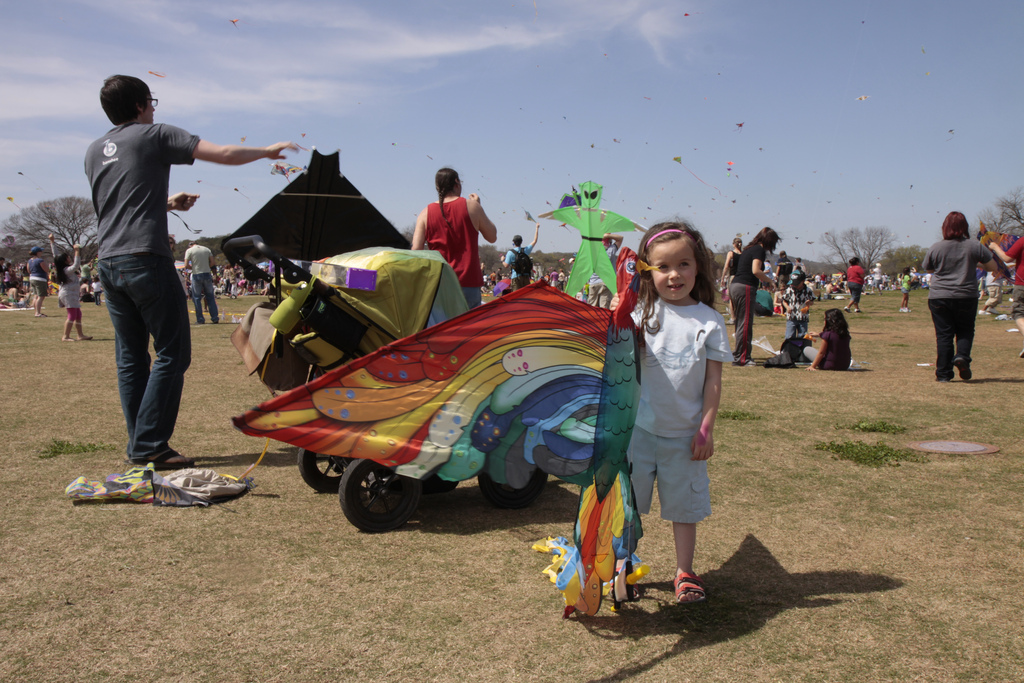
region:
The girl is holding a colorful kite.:
[220, 220, 759, 623]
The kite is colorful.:
[212, 253, 669, 607]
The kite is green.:
[528, 177, 640, 299]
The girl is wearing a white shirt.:
[612, 211, 731, 607]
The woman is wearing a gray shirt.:
[903, 206, 1011, 381]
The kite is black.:
[206, 130, 407, 268]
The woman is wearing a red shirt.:
[398, 154, 504, 301]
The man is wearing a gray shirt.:
[63, 81, 288, 467]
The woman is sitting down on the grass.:
[800, 307, 871, 390]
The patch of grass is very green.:
[802, 397, 923, 489]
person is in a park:
[87, 76, 297, 459]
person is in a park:
[602, 222, 724, 611]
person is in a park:
[509, 240, 535, 283]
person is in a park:
[727, 226, 784, 354]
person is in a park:
[813, 309, 853, 368]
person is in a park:
[924, 211, 992, 382]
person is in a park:
[49, 248, 85, 335]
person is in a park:
[181, 236, 224, 325]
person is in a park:
[503, 236, 535, 287]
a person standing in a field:
[614, 205, 685, 585]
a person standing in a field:
[25, 40, 241, 415]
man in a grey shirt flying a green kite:
[82, 72, 294, 468]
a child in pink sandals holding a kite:
[569, 218, 725, 615]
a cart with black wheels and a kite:
[230, 287, 579, 528]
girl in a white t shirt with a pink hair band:
[628, 220, 717, 312]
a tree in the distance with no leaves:
[0, 192, 92, 246]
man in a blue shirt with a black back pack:
[499, 222, 541, 289]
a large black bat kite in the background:
[228, 146, 410, 257]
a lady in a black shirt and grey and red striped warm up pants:
[727, 222, 782, 366]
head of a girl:
[633, 220, 706, 296]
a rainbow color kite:
[234, 284, 607, 490]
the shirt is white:
[626, 296, 729, 440]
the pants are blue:
[98, 245, 193, 458]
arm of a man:
[194, 134, 299, 167]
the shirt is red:
[433, 202, 479, 278]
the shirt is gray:
[918, 233, 988, 295]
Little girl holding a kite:
[219, 206, 748, 634]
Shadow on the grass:
[560, 512, 911, 674]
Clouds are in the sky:
[1, 0, 1016, 269]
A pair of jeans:
[83, 235, 201, 464]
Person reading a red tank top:
[399, 159, 505, 286]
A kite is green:
[528, 165, 655, 308]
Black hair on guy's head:
[90, 61, 167, 132]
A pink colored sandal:
[655, 544, 714, 605]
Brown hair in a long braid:
[422, 156, 473, 249]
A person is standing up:
[600, 201, 708, 603]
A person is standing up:
[56, 65, 292, 519]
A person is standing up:
[403, 168, 474, 287]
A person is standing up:
[499, 216, 550, 283]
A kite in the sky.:
[546, 169, 645, 293]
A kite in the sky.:
[580, 137, 594, 150]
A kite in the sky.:
[601, 134, 618, 145]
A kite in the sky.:
[664, 149, 680, 165]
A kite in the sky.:
[727, 157, 743, 170]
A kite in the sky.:
[852, 96, 865, 104]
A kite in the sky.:
[939, 124, 952, 134]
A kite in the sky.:
[906, 174, 914, 176]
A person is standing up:
[572, 226, 719, 599]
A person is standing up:
[78, 68, 278, 505]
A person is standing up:
[174, 223, 242, 322]